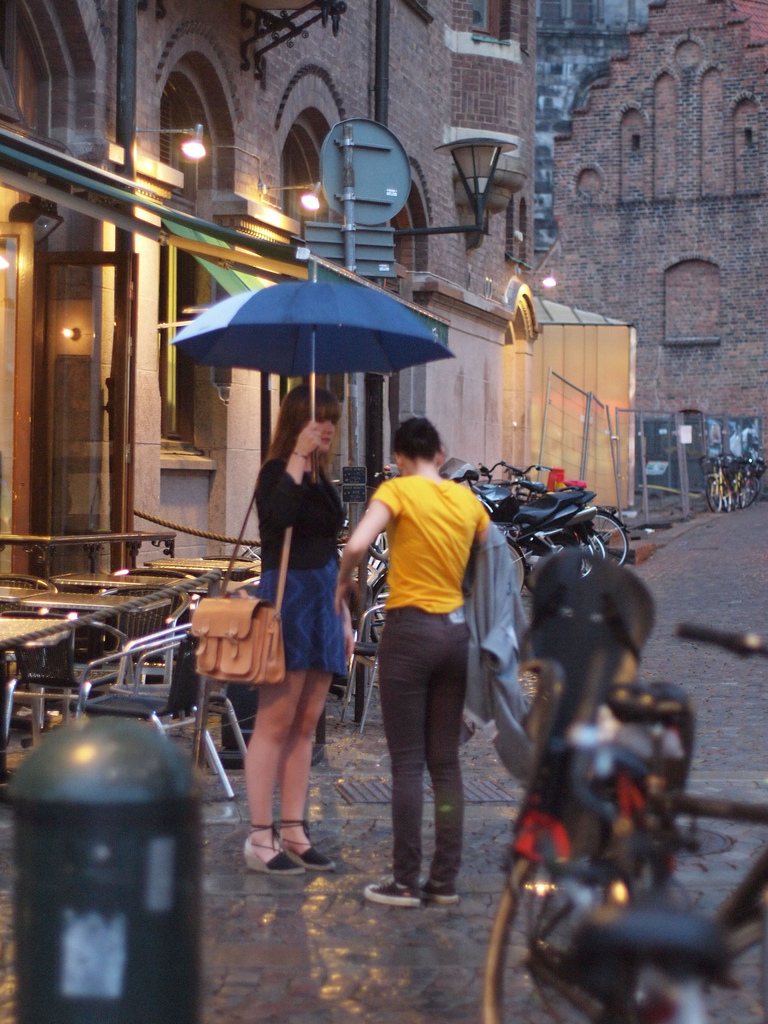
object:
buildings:
[12, 2, 768, 486]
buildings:
[531, 0, 768, 512]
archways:
[147, 33, 251, 208]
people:
[327, 403, 535, 926]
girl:
[233, 375, 353, 884]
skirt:
[247, 555, 358, 688]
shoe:
[360, 875, 424, 914]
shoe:
[240, 829, 309, 880]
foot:
[238, 834, 307, 879]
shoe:
[416, 869, 465, 910]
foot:
[360, 869, 427, 913]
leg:
[376, 600, 440, 904]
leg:
[426, 623, 473, 907]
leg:
[241, 568, 318, 879]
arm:
[328, 477, 405, 627]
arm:
[249, 416, 330, 547]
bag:
[185, 578, 297, 693]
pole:
[387, 136, 504, 244]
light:
[432, 130, 522, 233]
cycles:
[696, 446, 734, 516]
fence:
[575, 399, 761, 524]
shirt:
[365, 471, 495, 624]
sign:
[314, 107, 421, 234]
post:
[335, 116, 375, 625]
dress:
[241, 439, 356, 694]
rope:
[0, 561, 222, 657]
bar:
[0, 562, 230, 660]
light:
[57, 318, 82, 347]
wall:
[546, 4, 768, 477]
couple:
[233, 376, 503, 918]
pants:
[354, 592, 481, 925]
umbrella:
[167, 264, 462, 389]